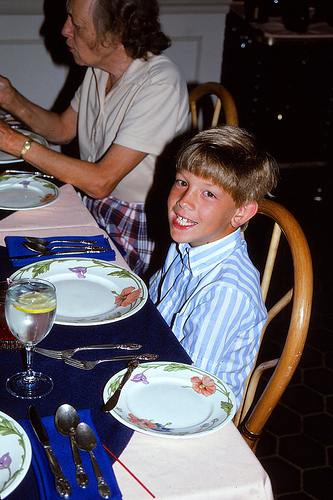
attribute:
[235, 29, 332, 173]
stove — black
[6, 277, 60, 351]
glass — clear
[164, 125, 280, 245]
boy — blond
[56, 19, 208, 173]
woman — older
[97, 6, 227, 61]
hair — brown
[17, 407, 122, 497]
napkin — blue, folded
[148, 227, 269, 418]
shirt — white, blue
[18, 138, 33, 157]
bracelet — gold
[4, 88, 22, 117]
wrist — womans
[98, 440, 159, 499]
straw — red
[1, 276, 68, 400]
glass — water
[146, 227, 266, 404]
shirt — blue, white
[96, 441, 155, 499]
straw — red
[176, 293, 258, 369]
cloth — table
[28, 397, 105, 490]
napkin — blue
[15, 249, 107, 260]
silverwear — undisturbed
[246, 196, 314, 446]
chair — wooden back, brown, wooden, dining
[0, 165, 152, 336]
table — white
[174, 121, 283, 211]
hair — blonde-brown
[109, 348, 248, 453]
design — flower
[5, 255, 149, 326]
plate — white, floral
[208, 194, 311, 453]
chair — wood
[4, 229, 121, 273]
napkin — blue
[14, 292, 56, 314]
wedge — lemon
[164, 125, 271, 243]
head — boys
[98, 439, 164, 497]
stick — red, stirrer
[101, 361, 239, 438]
china — fine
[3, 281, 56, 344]
liquid — clear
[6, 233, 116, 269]
napkin — blue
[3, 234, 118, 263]
napkin — blue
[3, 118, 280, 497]
cloth — table, white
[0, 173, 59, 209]
plate — floral